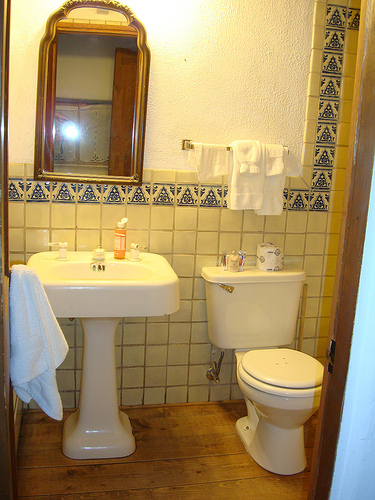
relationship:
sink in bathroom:
[28, 252, 181, 318] [12, 11, 315, 494]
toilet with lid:
[198, 252, 326, 477] [238, 343, 329, 399]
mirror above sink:
[32, 2, 155, 189] [28, 252, 181, 318]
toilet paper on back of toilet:
[253, 242, 289, 273] [198, 252, 326, 477]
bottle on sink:
[104, 215, 133, 259] [28, 252, 181, 318]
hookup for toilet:
[201, 355, 233, 386] [198, 252, 326, 477]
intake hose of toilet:
[207, 349, 227, 374] [198, 252, 326, 477]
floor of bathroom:
[19, 399, 321, 497] [12, 11, 315, 494]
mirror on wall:
[32, 2, 155, 189] [13, 8, 325, 405]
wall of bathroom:
[13, 8, 325, 405] [12, 11, 315, 494]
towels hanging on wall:
[226, 137, 291, 220] [13, 8, 325, 405]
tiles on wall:
[307, 8, 358, 215] [13, 8, 325, 405]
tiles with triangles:
[307, 8, 358, 215] [330, 34, 342, 48]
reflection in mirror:
[57, 114, 84, 140] [32, 2, 155, 189]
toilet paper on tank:
[253, 242, 289, 273] [198, 263, 304, 346]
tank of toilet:
[198, 263, 304, 346] [198, 252, 326, 477]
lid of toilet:
[238, 343, 329, 399] [198, 252, 326, 477]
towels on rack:
[226, 137, 291, 220] [184, 138, 297, 159]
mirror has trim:
[32, 2, 155, 189] [133, 38, 155, 183]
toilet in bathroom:
[198, 252, 326, 477] [12, 11, 315, 494]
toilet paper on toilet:
[253, 242, 289, 273] [198, 252, 326, 477]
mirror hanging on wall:
[32, 2, 155, 189] [13, 8, 325, 405]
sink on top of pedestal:
[28, 252, 181, 318] [61, 320, 135, 459]